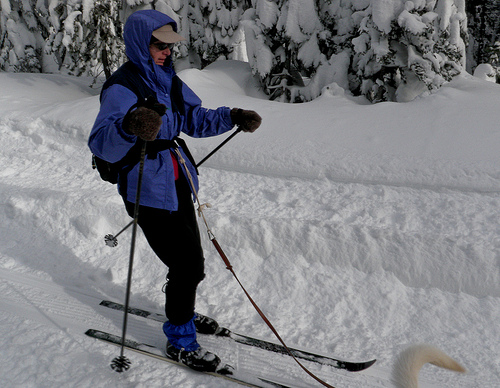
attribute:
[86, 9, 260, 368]
skier — gripping, standing, skiing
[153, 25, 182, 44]
hat — light brown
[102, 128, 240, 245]
ski pole — ski pole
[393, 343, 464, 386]
tail — white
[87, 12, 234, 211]
jacket — blue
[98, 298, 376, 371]
ski — black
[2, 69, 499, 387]
snow — white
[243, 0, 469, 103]
tree — covered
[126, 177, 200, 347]
pants — black, blue